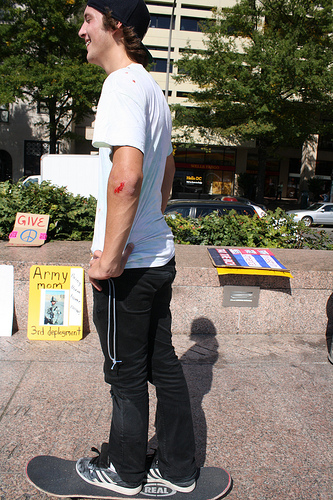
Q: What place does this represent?
A: It represents the sidewalk.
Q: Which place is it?
A: It is a sidewalk.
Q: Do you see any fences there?
A: No, there are no fences.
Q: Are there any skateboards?
A: Yes, there is a skateboard.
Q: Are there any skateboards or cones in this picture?
A: Yes, there is a skateboard.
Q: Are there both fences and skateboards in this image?
A: No, there is a skateboard but no fences.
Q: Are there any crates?
A: No, there are no crates.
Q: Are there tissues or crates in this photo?
A: No, there are no crates or tissues.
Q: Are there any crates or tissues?
A: No, there are no crates or tissues.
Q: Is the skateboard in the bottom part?
A: Yes, the skateboard is in the bottom of the image.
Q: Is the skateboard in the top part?
A: No, the skateboard is in the bottom of the image.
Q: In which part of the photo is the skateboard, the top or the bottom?
A: The skateboard is in the bottom of the image.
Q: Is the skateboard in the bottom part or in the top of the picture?
A: The skateboard is in the bottom of the image.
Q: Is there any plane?
A: No, there are no airplanes.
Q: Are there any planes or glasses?
A: No, there are no planes or glasses.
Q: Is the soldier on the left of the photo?
A: Yes, the soldier is on the left of the image.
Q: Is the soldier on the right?
A: No, the soldier is on the left of the image.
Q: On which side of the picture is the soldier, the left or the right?
A: The soldier is on the left of the image.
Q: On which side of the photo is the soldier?
A: The soldier is on the left of the image.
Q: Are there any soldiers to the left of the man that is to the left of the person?
A: Yes, there is a soldier to the left of the man.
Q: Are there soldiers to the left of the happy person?
A: Yes, there is a soldier to the left of the man.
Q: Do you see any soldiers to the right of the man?
A: No, the soldier is to the left of the man.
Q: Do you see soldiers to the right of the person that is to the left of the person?
A: No, the soldier is to the left of the man.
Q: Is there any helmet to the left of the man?
A: No, there is a soldier to the left of the man.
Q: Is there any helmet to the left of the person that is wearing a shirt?
A: No, there is a soldier to the left of the man.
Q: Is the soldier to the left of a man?
A: Yes, the soldier is to the left of a man.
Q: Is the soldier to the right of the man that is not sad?
A: No, the soldier is to the left of the man.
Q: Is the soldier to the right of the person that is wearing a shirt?
A: No, the soldier is to the left of the man.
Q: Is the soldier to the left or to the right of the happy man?
A: The soldier is to the left of the man.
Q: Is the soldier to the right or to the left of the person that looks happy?
A: The soldier is to the left of the man.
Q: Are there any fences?
A: No, there are no fences.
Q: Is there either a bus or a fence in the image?
A: No, there are no fences or buses.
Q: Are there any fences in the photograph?
A: No, there are no fences.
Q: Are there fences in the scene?
A: No, there are no fences.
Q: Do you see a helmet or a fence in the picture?
A: No, there are no fences or helmets.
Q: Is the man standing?
A: Yes, the man is standing.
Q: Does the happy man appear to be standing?
A: Yes, the man is standing.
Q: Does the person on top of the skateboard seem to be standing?
A: Yes, the man is standing.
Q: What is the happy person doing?
A: The man is standing.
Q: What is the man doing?
A: The man is standing.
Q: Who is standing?
A: The man is standing.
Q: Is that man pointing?
A: No, the man is standing.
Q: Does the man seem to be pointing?
A: No, the man is standing.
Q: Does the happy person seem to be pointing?
A: No, the man is standing.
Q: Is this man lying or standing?
A: The man is standing.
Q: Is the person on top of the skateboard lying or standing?
A: The man is standing.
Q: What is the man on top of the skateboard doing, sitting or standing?
A: The man is standing.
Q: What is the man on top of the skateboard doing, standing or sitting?
A: The man is standing.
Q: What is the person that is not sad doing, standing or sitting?
A: The man is standing.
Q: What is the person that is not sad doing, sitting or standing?
A: The man is standing.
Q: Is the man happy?
A: Yes, the man is happy.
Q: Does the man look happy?
A: Yes, the man is happy.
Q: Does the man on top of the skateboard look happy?
A: Yes, the man is happy.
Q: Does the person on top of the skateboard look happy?
A: Yes, the man is happy.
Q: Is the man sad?
A: No, the man is happy.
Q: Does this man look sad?
A: No, the man is happy.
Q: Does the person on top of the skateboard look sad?
A: No, the man is happy.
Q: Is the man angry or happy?
A: The man is happy.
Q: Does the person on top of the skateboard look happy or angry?
A: The man is happy.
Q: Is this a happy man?
A: Yes, this is a happy man.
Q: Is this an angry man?
A: No, this is a happy man.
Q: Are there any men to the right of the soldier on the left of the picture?
A: Yes, there is a man to the right of the soldier.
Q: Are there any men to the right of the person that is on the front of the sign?
A: Yes, there is a man to the right of the soldier.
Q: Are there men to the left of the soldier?
A: No, the man is to the right of the soldier.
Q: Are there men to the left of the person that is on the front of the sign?
A: No, the man is to the right of the soldier.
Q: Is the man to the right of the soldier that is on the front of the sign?
A: Yes, the man is to the right of the soldier.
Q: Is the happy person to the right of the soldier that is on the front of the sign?
A: Yes, the man is to the right of the soldier.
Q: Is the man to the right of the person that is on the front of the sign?
A: Yes, the man is to the right of the soldier.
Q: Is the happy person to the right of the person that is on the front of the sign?
A: Yes, the man is to the right of the soldier.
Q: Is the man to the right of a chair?
A: No, the man is to the right of the soldier.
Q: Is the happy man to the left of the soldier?
A: No, the man is to the right of the soldier.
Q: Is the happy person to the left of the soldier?
A: No, the man is to the right of the soldier.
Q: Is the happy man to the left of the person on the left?
A: No, the man is to the right of the soldier.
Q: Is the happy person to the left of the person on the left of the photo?
A: No, the man is to the right of the soldier.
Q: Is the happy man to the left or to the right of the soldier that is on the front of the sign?
A: The man is to the right of the soldier.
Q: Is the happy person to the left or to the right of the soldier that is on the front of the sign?
A: The man is to the right of the soldier.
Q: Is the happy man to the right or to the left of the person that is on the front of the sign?
A: The man is to the right of the soldier.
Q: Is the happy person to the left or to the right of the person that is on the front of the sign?
A: The man is to the right of the soldier.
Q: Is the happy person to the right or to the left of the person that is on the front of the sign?
A: The man is to the right of the soldier.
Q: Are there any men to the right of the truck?
A: Yes, there is a man to the right of the truck.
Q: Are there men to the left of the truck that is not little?
A: No, the man is to the right of the truck.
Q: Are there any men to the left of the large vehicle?
A: No, the man is to the right of the truck.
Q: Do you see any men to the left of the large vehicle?
A: No, the man is to the right of the truck.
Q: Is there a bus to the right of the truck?
A: No, there is a man to the right of the truck.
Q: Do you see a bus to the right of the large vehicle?
A: No, there is a man to the right of the truck.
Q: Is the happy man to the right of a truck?
A: Yes, the man is to the right of a truck.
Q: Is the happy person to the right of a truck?
A: Yes, the man is to the right of a truck.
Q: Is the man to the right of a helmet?
A: No, the man is to the right of a truck.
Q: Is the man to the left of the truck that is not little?
A: No, the man is to the right of the truck.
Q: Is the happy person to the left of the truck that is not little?
A: No, the man is to the right of the truck.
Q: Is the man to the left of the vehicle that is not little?
A: No, the man is to the right of the truck.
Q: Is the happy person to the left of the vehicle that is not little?
A: No, the man is to the right of the truck.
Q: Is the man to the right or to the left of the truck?
A: The man is to the right of the truck.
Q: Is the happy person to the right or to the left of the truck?
A: The man is to the right of the truck.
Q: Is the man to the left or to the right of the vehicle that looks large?
A: The man is to the right of the truck.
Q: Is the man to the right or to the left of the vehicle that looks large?
A: The man is to the right of the truck.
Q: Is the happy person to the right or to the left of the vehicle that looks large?
A: The man is to the right of the truck.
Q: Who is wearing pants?
A: The man is wearing pants.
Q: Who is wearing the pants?
A: The man is wearing pants.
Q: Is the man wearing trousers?
A: Yes, the man is wearing trousers.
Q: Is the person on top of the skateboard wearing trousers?
A: Yes, the man is wearing trousers.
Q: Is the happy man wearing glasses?
A: No, the man is wearing trousers.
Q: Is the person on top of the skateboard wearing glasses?
A: No, the man is wearing trousers.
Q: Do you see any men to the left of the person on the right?
A: Yes, there is a man to the left of the person.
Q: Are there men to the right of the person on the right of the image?
A: No, the man is to the left of the person.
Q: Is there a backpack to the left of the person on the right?
A: No, there is a man to the left of the person.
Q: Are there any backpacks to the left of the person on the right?
A: No, there is a man to the left of the person.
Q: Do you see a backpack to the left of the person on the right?
A: No, there is a man to the left of the person.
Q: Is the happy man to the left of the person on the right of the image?
A: Yes, the man is to the left of the person.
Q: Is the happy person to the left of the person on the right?
A: Yes, the man is to the left of the person.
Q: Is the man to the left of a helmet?
A: No, the man is to the left of the person.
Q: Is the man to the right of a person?
A: No, the man is to the left of a person.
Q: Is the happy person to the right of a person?
A: No, the man is to the left of a person.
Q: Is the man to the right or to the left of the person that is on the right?
A: The man is to the left of the person.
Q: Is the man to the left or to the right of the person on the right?
A: The man is to the left of the person.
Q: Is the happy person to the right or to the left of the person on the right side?
A: The man is to the left of the person.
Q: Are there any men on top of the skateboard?
A: Yes, there is a man on top of the skateboard.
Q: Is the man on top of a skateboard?
A: Yes, the man is on top of a skateboard.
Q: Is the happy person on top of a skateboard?
A: Yes, the man is on top of a skateboard.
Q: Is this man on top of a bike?
A: No, the man is on top of a skateboard.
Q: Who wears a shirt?
A: The man wears a shirt.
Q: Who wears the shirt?
A: The man wears a shirt.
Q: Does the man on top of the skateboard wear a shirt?
A: Yes, the man wears a shirt.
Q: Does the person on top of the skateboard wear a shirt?
A: Yes, the man wears a shirt.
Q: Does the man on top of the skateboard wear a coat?
A: No, the man wears a shirt.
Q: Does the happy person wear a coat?
A: No, the man wears a shirt.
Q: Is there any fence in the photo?
A: No, there are no fences.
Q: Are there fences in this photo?
A: No, there are no fences.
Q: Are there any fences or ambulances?
A: No, there are no fences or ambulances.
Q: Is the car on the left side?
A: No, the car is on the right of the image.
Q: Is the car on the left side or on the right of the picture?
A: The car is on the right of the image.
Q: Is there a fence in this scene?
A: No, there are no fences.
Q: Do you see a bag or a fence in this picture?
A: No, there are no fences or bags.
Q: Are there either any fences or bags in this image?
A: No, there are no fences or bags.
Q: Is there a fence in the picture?
A: No, there are no fences.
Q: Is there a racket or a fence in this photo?
A: No, there are no fences or rackets.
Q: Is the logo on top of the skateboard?
A: Yes, the logo is on top of the skateboard.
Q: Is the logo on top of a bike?
A: No, the logo is on top of the skateboard.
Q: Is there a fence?
A: No, there are no fences.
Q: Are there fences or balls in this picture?
A: No, there are no fences or balls.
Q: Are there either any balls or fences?
A: No, there are no fences or balls.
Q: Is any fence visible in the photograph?
A: No, there are no fences.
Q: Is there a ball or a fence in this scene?
A: No, there are no fences or balls.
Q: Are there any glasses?
A: No, there are no glasses.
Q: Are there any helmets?
A: No, there are no helmets.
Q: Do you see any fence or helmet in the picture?
A: No, there are no helmets or fences.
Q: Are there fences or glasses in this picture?
A: No, there are no fences or glasses.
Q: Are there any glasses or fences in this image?
A: No, there are no fences or glasses.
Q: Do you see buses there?
A: No, there are no buses.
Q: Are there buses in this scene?
A: No, there are no buses.